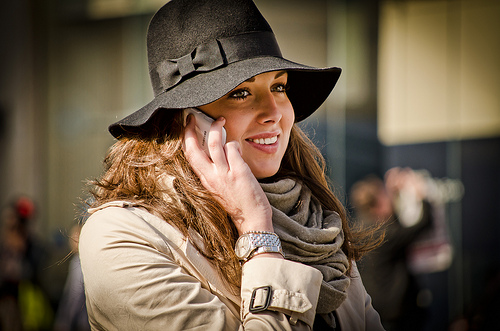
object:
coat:
[75, 202, 385, 330]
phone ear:
[179, 104, 228, 157]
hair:
[51, 83, 391, 298]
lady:
[74, 0, 384, 331]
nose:
[256, 79, 283, 125]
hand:
[181, 111, 275, 224]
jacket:
[351, 198, 432, 322]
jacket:
[38, 252, 93, 327]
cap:
[106, 0, 343, 142]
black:
[170, 47, 233, 79]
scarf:
[253, 175, 355, 322]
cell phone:
[182, 104, 227, 158]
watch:
[232, 230, 286, 261]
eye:
[227, 87, 253, 101]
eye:
[269, 81, 288, 93]